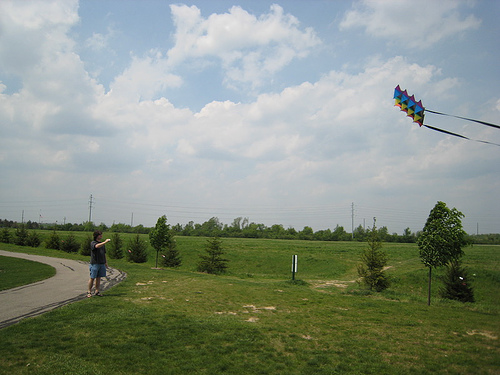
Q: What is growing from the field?
A: Grass and trees.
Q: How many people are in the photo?
A: 1.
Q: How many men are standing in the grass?
A: 1.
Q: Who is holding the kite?
A: The man.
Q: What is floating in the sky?
A: A kite.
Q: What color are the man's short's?
A: Blue.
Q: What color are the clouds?
A: White.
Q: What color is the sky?
A: Blue.